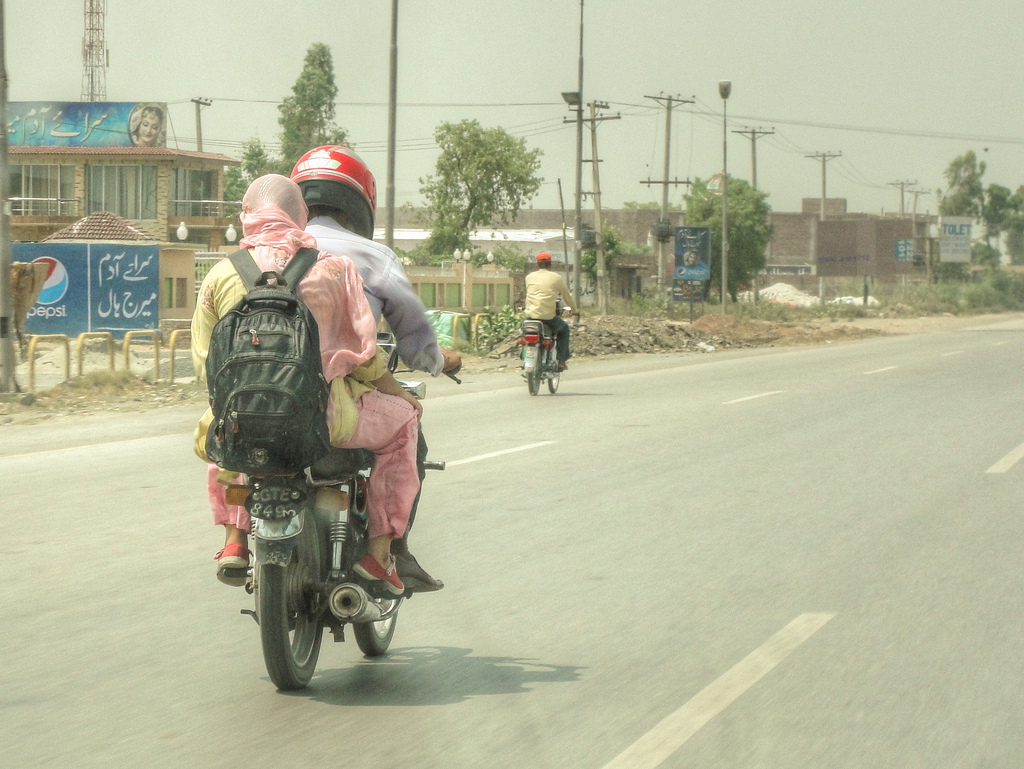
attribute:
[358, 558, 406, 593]
shoe — red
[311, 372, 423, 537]
pants — pink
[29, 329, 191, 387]
fencepoles — yellow, metal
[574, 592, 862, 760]
white lines — dotted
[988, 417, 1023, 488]
white lines — dotted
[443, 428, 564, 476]
white lines — dotted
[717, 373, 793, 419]
white lines — dotted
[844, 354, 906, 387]
white lines — dotted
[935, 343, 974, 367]
white lines — dotted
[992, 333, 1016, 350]
white lines — dotted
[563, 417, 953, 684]
street — light grey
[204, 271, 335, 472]
backpack — black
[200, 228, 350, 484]
backpack — black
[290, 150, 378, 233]
helmet — red